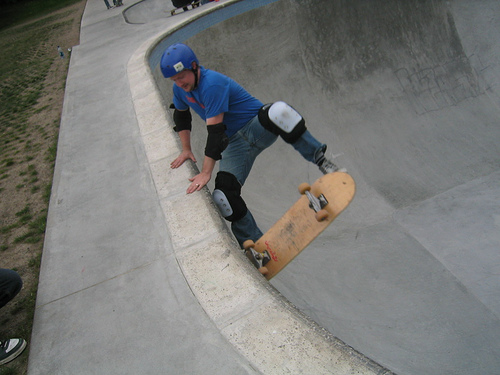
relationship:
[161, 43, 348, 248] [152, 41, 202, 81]
man wearing helmet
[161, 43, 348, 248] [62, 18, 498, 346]
man skating at skating ring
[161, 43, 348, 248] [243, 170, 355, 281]
man skating on skateboard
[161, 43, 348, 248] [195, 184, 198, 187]
man wearing ring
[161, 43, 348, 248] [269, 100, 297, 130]
man wearing pads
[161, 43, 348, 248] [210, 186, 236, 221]
man wearing pads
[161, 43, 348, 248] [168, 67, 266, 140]
man wearing shirt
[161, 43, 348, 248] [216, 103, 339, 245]
man wearing jeans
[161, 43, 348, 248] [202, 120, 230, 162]
man wearing elbow pads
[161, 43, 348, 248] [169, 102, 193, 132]
man wearing elbow pads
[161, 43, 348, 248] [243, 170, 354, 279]
man riding skateboard